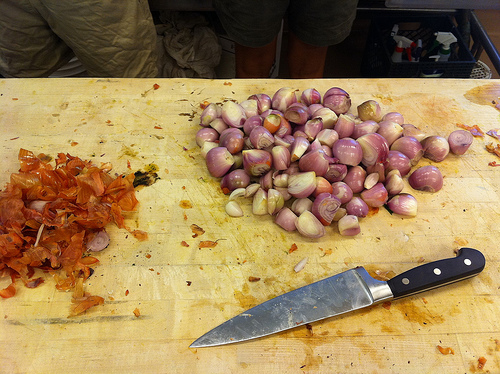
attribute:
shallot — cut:
[409, 165, 444, 192]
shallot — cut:
[449, 123, 471, 153]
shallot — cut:
[338, 215, 359, 235]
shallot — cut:
[333, 138, 361, 165]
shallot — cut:
[293, 208, 324, 239]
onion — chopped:
[330, 135, 365, 166]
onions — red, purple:
[211, 81, 408, 212]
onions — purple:
[196, 87, 473, 226]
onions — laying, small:
[200, 79, 471, 246]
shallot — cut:
[268, 110, 302, 138]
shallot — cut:
[448, 127, 473, 156]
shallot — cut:
[388, 192, 419, 217]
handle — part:
[388, 246, 488, 309]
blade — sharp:
[178, 264, 383, 351]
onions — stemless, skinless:
[195, 78, 487, 240]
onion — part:
[177, 72, 478, 255]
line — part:
[156, 258, 189, 272]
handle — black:
[387, 238, 493, 300]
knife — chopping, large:
[180, 236, 495, 361]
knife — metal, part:
[190, 243, 487, 350]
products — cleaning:
[388, 23, 400, 38]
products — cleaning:
[388, 32, 418, 63]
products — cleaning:
[407, 35, 428, 62]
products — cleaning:
[433, 29, 456, 66]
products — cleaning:
[423, 50, 445, 83]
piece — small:
[212, 142, 243, 188]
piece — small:
[284, 102, 310, 129]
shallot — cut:
[273, 82, 295, 104]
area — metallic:
[178, 254, 401, 358]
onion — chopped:
[329, 144, 459, 218]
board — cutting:
[6, 72, 498, 367]